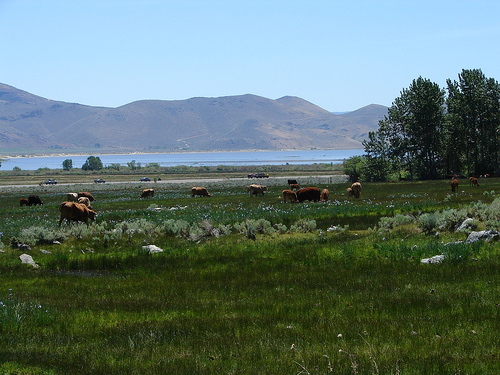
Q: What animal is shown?
A: Cattle.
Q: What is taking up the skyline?
A: Mountains.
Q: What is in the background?
A: Line of hills.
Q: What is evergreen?
A: Grouping of trees.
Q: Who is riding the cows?
A: No one.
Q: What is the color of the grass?
A: Green.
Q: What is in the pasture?
A: Green trees.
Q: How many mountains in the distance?
A: One.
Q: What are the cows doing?
A: Grazing in the field.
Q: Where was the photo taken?
A: Field.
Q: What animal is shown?
A: Cow.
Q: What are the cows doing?
A: Eating.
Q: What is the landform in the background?
A: Mountains.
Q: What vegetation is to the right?
A: Trees.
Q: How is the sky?
A: Blue.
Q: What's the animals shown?
A: Cows.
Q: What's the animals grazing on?
A: Grass.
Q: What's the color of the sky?
A: Blue.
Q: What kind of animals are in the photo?
A: Cows.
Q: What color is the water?
A: Blue.